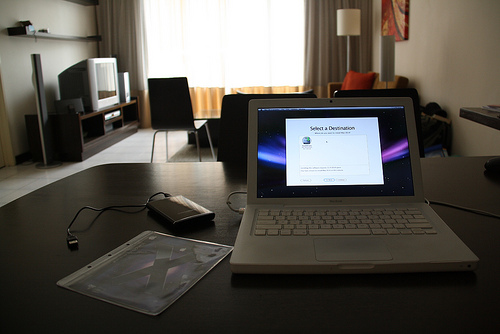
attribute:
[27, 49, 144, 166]
entertainment center — dark, wooden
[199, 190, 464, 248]
keyboard — gray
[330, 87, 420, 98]
loveseat — cloth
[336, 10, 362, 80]
lamp — metal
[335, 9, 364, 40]
shade — white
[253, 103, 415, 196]
screen — on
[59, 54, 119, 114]
tv — older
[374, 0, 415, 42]
painting — warm-colored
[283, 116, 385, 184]
window — open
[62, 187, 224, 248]
hardrive — external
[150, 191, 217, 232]
hard drive — portable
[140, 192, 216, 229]
hard drive — portable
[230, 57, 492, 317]
laptop — open, on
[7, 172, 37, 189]
tile — white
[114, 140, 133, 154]
tile — white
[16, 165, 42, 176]
tile — white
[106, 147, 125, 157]
tile — white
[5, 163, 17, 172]
tile — white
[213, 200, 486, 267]
keyboard — white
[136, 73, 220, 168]
chair — black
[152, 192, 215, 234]
hard drive — black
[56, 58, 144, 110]
television — powered off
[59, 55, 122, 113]
television — old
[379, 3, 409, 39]
painting — colorful